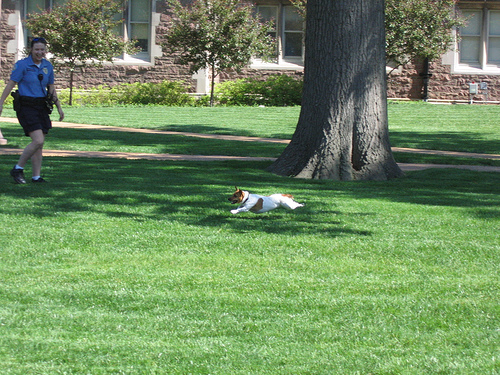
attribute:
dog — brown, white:
[227, 185, 302, 214]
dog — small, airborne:
[219, 183, 306, 222]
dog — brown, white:
[228, 190, 308, 223]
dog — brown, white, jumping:
[224, 187, 304, 217]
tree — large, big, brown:
[264, 4, 402, 186]